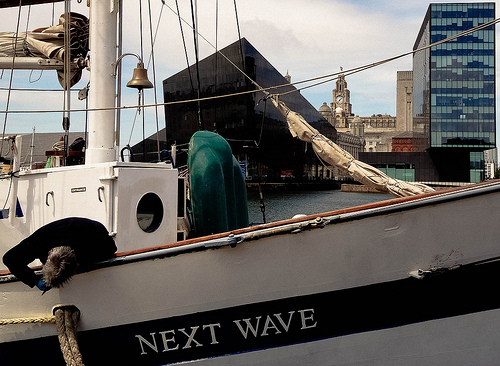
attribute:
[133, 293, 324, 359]
writing — white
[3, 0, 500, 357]
boat — white, navy, large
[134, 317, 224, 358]
word — next, ext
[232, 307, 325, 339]
word — wave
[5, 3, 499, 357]
part — white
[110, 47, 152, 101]
bell — small, gold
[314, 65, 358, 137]
building — black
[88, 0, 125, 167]
pole — white, large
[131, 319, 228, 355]
letters — white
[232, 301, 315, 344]
lettering — white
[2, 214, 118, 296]
man — here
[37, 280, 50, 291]
glove — blue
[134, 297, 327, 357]
letters — white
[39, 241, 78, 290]
hair — grey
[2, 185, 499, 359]
side — black, white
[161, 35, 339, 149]
building — here, black, large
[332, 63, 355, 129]
tower — brown, tall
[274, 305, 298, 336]
letter — white, v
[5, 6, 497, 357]
picture — boat, rope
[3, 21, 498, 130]
rope — here, light brown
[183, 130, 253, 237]
seat — here, green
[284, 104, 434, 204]
mast — rolled up, boat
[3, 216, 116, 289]
person — here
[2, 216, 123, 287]
jacket — black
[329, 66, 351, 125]
clock tower — large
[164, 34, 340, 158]
office building — large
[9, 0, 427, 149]
sky — cloudy, blue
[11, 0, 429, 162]
harbor — here